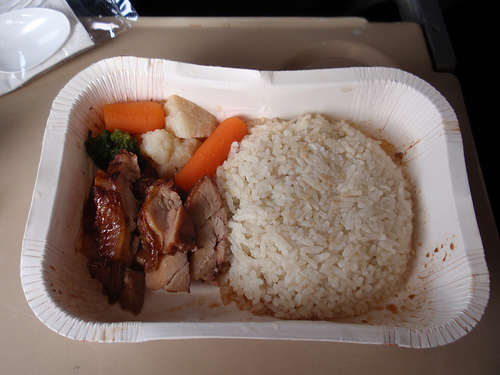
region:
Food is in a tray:
[20, 55, 490, 348]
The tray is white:
[18, 56, 489, 349]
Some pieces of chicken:
[85, 149, 227, 314]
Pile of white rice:
[218, 112, 414, 322]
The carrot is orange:
[177, 116, 244, 191]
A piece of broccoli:
[83, 130, 135, 166]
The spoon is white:
[0, 7, 69, 72]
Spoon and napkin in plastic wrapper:
[0, 0, 135, 95]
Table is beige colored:
[0, 17, 498, 372]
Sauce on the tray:
[382, 241, 454, 321]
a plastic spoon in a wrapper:
[1, 4, 71, 77]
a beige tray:
[0, 17, 499, 372]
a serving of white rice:
[220, 115, 414, 317]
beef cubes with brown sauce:
[86, 151, 226, 311]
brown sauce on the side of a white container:
[363, 228, 465, 329]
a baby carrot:
[173, 115, 243, 190]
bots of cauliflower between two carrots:
[138, 95, 214, 173]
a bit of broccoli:
[82, 127, 133, 166]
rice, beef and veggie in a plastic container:
[83, 96, 415, 316]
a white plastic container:
[19, 57, 491, 347]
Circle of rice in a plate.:
[260, 119, 395, 301]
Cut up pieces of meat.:
[93, 173, 138, 263]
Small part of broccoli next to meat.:
[88, 130, 142, 164]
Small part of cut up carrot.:
[98, 98, 171, 133]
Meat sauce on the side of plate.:
[428, 228, 463, 285]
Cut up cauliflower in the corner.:
[170, 98, 219, 140]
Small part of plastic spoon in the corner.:
[1, 2, 76, 74]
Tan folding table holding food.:
[243, 14, 425, 64]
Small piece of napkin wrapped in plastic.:
[67, 8, 151, 48]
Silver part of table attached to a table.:
[396, 1, 468, 71]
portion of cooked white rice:
[213, 114, 413, 323]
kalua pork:
[88, 150, 228, 313]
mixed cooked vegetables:
[85, 95, 247, 191]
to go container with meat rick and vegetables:
[21, 56, 490, 348]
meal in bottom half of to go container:
[21, 55, 490, 350]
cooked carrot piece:
[177, 117, 247, 193]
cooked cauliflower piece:
[164, 95, 218, 139]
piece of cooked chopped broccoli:
[84, 126, 133, 160]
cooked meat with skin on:
[82, 153, 231, 310]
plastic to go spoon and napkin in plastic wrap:
[3, 1, 135, 93]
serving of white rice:
[230, 131, 417, 312]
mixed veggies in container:
[99, 104, 244, 178]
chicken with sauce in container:
[89, 162, 221, 299]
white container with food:
[69, 65, 497, 329]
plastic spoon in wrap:
[3, 3, 101, 81]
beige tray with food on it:
[1, 28, 488, 372]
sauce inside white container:
[57, 252, 124, 307]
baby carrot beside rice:
[167, 117, 245, 174]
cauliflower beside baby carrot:
[145, 105, 212, 146]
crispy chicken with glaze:
[91, 187, 221, 263]